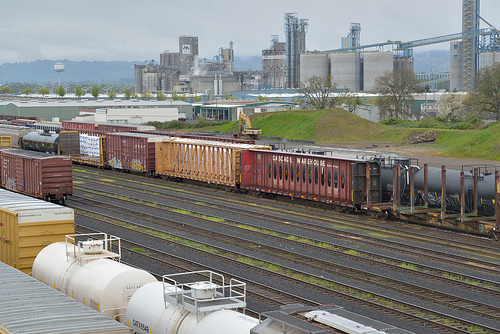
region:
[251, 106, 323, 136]
the grass is green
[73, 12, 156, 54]
the sky is gray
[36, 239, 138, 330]
the tank is white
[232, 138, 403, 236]
the cargo carrier is red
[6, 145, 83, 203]
the cargo container is maroon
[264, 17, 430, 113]
the plant is gray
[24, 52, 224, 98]
the mountains are in the distance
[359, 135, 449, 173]
the soil is brown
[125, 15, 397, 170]
the buildings are tall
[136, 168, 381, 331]
the tracks are black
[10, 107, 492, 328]
A train yard with multiple tracks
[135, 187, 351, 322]
There is grass between each track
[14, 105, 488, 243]
There are orange cars, red cars, and black tanks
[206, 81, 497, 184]
A green hill is with trees is next to the train yard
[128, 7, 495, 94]
Grey and beige buildings of different heights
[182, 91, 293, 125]
Green and white building with windows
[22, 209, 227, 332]
Two white tank cars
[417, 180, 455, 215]
White graffiti on the black tank car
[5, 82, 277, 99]
A line of green trees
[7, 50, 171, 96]
Blue mountains in the background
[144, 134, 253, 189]
yellow freight car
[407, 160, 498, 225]
black tanker on train tracks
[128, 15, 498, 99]
refinery in the background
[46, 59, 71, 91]
white water tower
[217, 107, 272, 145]
yellow backhoe near a hill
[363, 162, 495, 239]
rusted skeleton of freight car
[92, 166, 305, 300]
grass between train tracks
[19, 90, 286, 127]
river bisecting land mass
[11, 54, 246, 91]
forested hills in the background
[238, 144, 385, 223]
red train car with white lettering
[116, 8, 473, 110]
factory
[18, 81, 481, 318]
train yard with cargo train cars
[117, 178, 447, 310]
train tracks in train yard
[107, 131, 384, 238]
three train cars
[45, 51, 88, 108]
water tower and trees with green leaves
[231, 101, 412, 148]
hills with green grass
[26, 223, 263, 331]
two white fuel tankers in train yard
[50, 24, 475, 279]
factory and train yard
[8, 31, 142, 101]
mountains in the distance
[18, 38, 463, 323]
factory and box cars in trail yard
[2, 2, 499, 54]
the cloudy sky above everything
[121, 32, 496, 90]
the tall buildings and factories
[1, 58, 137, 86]
the hill in the background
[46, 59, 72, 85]
the water tower in the background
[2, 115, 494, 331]
the many trains on the tracks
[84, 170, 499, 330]
the empty train tracks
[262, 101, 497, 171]
some green grass next to the tracks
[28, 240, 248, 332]
some white train cars on the track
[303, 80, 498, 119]
some trees next to the grass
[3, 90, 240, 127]
some buildings next to the tracks